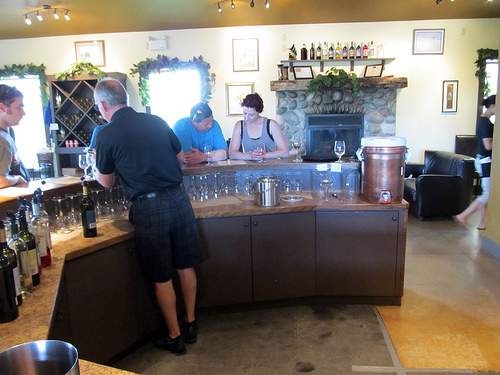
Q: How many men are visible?
A: Three.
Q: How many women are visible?
A: Two.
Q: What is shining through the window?
A: Light.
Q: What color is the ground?
A: Brown.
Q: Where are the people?
A: At the bar.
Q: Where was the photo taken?
A: At a bar.